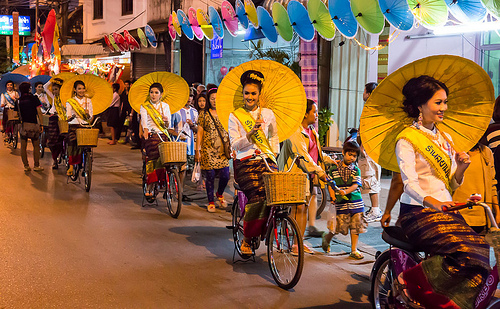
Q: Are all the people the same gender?
A: No, they are both male and female.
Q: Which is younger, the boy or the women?
A: The boy is younger than the women.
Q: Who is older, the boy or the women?
A: The women is older than the boy.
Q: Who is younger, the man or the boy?
A: The boy is younger than the man.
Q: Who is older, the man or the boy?
A: The man is older than the boy.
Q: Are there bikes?
A: Yes, there is a bike.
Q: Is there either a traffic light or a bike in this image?
A: Yes, there is a bike.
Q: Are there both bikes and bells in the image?
A: No, there is a bike but no bells.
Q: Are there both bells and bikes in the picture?
A: No, there is a bike but no bells.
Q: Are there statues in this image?
A: No, there are no statues.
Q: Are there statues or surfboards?
A: No, there are no statues or surfboards.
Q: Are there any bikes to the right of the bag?
A: Yes, there is a bike to the right of the bag.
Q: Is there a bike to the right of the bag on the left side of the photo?
A: Yes, there is a bike to the right of the bag.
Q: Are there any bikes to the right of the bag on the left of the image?
A: Yes, there is a bike to the right of the bag.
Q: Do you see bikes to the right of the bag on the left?
A: Yes, there is a bike to the right of the bag.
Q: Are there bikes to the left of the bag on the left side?
A: No, the bike is to the right of the bag.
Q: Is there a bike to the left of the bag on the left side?
A: No, the bike is to the right of the bag.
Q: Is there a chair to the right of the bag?
A: No, there is a bike to the right of the bag.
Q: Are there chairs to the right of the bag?
A: No, there is a bike to the right of the bag.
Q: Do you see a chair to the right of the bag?
A: No, there is a bike to the right of the bag.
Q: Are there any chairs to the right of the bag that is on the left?
A: No, there is a bike to the right of the bag.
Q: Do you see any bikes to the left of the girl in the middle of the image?
A: Yes, there is a bike to the left of the girl.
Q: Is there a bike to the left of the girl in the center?
A: Yes, there is a bike to the left of the girl.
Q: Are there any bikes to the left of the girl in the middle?
A: Yes, there is a bike to the left of the girl.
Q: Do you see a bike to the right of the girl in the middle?
A: No, the bike is to the left of the girl.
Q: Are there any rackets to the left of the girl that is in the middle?
A: No, there is a bike to the left of the girl.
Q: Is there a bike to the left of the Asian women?
A: Yes, there is a bike to the left of the women.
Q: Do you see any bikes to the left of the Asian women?
A: Yes, there is a bike to the left of the women.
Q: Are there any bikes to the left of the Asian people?
A: Yes, there is a bike to the left of the women.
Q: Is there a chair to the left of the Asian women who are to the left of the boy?
A: No, there is a bike to the left of the women.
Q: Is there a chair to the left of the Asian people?
A: No, there is a bike to the left of the women.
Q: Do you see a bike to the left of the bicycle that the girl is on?
A: Yes, there is a bike to the left of the bicycle.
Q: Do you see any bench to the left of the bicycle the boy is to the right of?
A: No, there is a bike to the left of the bicycle.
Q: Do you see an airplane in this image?
A: No, there are no airplanes.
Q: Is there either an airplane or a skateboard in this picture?
A: No, there are no airplanes or skateboards.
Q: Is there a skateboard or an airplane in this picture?
A: No, there are no airplanes or skateboards.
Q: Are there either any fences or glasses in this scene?
A: No, there are no fences or glasses.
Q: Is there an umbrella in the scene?
A: Yes, there is an umbrella.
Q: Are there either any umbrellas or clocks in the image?
A: Yes, there is an umbrella.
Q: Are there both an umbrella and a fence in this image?
A: No, there is an umbrella but no fences.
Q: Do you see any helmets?
A: No, there are no helmets.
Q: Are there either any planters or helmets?
A: No, there are no helmets or planters.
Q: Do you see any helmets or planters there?
A: No, there are no helmets or planters.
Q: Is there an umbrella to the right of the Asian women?
A: Yes, there is an umbrella to the right of the women.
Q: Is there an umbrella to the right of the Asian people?
A: Yes, there is an umbrella to the right of the women.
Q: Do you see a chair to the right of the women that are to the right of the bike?
A: No, there is an umbrella to the right of the women.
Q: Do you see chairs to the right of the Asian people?
A: No, there is an umbrella to the right of the women.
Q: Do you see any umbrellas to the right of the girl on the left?
A: Yes, there is an umbrella to the right of the girl.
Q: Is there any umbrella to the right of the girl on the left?
A: Yes, there is an umbrella to the right of the girl.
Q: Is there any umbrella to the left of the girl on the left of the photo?
A: No, the umbrella is to the right of the girl.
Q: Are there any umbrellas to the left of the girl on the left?
A: No, the umbrella is to the right of the girl.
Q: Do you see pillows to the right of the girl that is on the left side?
A: No, there is an umbrella to the right of the girl.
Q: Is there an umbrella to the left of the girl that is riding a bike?
A: Yes, there is an umbrella to the left of the girl.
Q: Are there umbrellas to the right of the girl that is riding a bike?
A: No, the umbrella is to the left of the girl.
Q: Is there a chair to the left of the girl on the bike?
A: No, there is an umbrella to the left of the girl.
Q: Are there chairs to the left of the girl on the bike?
A: No, there is an umbrella to the left of the girl.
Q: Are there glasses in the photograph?
A: No, there are no glasses.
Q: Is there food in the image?
A: No, there is no food.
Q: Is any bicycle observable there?
A: Yes, there is a bicycle.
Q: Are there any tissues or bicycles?
A: Yes, there is a bicycle.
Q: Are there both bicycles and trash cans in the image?
A: No, there is a bicycle but no trash cans.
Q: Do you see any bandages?
A: No, there are no bandages.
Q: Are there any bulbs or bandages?
A: No, there are no bandages or bulbs.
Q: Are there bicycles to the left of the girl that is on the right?
A: Yes, there is a bicycle to the left of the girl.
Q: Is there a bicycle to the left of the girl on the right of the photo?
A: Yes, there is a bicycle to the left of the girl.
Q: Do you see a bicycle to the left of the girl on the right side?
A: Yes, there is a bicycle to the left of the girl.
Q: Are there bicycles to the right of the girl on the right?
A: No, the bicycle is to the left of the girl.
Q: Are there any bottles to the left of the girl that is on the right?
A: No, there is a bicycle to the left of the girl.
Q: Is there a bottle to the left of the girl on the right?
A: No, there is a bicycle to the left of the girl.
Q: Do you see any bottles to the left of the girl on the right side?
A: No, there is a bicycle to the left of the girl.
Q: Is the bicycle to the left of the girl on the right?
A: Yes, the bicycle is to the left of the girl.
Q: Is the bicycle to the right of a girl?
A: No, the bicycle is to the left of a girl.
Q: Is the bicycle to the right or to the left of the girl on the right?
A: The bicycle is to the left of the girl.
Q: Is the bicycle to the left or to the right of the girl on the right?
A: The bicycle is to the left of the girl.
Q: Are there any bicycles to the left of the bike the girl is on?
A: Yes, there is a bicycle to the left of the bike.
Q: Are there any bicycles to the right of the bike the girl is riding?
A: No, the bicycle is to the left of the bike.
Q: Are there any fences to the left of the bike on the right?
A: No, there is a bicycle to the left of the bike.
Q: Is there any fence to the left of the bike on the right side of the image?
A: No, there is a bicycle to the left of the bike.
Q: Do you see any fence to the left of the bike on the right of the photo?
A: No, there is a bicycle to the left of the bike.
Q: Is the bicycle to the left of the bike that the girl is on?
A: Yes, the bicycle is to the left of the bike.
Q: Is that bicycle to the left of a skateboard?
A: No, the bicycle is to the left of the bike.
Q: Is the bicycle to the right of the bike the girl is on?
A: No, the bicycle is to the left of the bike.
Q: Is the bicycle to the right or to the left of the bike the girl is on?
A: The bicycle is to the left of the bike.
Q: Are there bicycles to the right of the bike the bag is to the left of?
A: Yes, there is a bicycle to the right of the bike.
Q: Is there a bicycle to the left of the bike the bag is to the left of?
A: No, the bicycle is to the right of the bike.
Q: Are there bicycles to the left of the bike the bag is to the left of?
A: No, the bicycle is to the right of the bike.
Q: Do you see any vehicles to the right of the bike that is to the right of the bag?
A: No, there is a bicycle to the right of the bike.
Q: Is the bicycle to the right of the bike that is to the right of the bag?
A: Yes, the bicycle is to the right of the bike.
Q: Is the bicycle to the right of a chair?
A: No, the bicycle is to the right of the bike.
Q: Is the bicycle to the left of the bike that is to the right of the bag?
A: No, the bicycle is to the right of the bike.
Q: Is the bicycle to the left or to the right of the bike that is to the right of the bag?
A: The bicycle is to the right of the bike.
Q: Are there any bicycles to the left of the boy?
A: Yes, there is a bicycle to the left of the boy.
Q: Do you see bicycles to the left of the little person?
A: Yes, there is a bicycle to the left of the boy.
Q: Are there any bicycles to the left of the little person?
A: Yes, there is a bicycle to the left of the boy.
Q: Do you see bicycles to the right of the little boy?
A: No, the bicycle is to the left of the boy.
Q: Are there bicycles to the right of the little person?
A: No, the bicycle is to the left of the boy.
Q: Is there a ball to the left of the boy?
A: No, there is a bicycle to the left of the boy.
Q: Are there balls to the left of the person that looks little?
A: No, there is a bicycle to the left of the boy.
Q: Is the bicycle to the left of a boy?
A: Yes, the bicycle is to the left of a boy.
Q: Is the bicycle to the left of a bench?
A: No, the bicycle is to the left of a boy.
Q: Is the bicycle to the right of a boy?
A: No, the bicycle is to the left of a boy.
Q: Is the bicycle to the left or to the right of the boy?
A: The bicycle is to the left of the boy.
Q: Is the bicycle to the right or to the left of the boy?
A: The bicycle is to the left of the boy.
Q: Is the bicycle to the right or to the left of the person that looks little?
A: The bicycle is to the left of the boy.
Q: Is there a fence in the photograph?
A: No, there are no fences.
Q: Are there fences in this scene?
A: No, there are no fences.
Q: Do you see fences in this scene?
A: No, there are no fences.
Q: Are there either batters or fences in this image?
A: No, there are no fences or batters.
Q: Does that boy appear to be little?
A: Yes, the boy is little.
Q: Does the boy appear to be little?
A: Yes, the boy is little.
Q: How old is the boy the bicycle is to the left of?
A: The boy is little.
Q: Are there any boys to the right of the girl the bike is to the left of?
A: Yes, there is a boy to the right of the girl.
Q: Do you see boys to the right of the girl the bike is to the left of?
A: Yes, there is a boy to the right of the girl.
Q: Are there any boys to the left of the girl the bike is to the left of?
A: No, the boy is to the right of the girl.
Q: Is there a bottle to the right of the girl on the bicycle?
A: No, there is a boy to the right of the girl.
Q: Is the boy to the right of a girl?
A: Yes, the boy is to the right of a girl.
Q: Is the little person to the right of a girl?
A: Yes, the boy is to the right of a girl.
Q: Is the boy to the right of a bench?
A: No, the boy is to the right of a girl.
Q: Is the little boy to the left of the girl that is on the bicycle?
A: No, the boy is to the right of the girl.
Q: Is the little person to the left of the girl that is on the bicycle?
A: No, the boy is to the right of the girl.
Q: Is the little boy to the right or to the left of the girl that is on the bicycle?
A: The boy is to the right of the girl.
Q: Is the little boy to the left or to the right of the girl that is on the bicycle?
A: The boy is to the right of the girl.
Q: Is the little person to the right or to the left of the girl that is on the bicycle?
A: The boy is to the right of the girl.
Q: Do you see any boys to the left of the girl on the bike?
A: Yes, there is a boy to the left of the girl.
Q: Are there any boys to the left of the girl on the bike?
A: Yes, there is a boy to the left of the girl.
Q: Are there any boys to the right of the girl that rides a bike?
A: No, the boy is to the left of the girl.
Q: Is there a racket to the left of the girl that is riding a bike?
A: No, there is a boy to the left of the girl.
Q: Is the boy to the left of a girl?
A: Yes, the boy is to the left of a girl.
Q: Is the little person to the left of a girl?
A: Yes, the boy is to the left of a girl.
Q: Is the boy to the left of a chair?
A: No, the boy is to the left of a girl.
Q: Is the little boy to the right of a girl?
A: No, the boy is to the left of a girl.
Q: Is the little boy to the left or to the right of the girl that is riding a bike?
A: The boy is to the left of the girl.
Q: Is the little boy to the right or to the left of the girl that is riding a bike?
A: The boy is to the left of the girl.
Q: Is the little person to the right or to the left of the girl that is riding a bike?
A: The boy is to the left of the girl.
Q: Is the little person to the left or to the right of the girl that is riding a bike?
A: The boy is to the left of the girl.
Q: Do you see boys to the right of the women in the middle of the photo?
A: Yes, there is a boy to the right of the women.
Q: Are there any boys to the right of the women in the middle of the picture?
A: Yes, there is a boy to the right of the women.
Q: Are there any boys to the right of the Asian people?
A: Yes, there is a boy to the right of the women.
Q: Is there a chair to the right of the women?
A: No, there is a boy to the right of the women.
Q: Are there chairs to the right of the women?
A: No, there is a boy to the right of the women.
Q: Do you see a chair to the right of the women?
A: No, there is a boy to the right of the women.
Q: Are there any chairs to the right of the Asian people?
A: No, there is a boy to the right of the women.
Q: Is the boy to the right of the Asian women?
A: Yes, the boy is to the right of the women.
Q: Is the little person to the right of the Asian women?
A: Yes, the boy is to the right of the women.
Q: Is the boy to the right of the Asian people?
A: Yes, the boy is to the right of the women.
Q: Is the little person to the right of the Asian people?
A: Yes, the boy is to the right of the women.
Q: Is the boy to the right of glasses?
A: No, the boy is to the right of the women.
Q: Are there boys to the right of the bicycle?
A: Yes, there is a boy to the right of the bicycle.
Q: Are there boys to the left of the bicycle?
A: No, the boy is to the right of the bicycle.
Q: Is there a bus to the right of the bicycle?
A: No, there is a boy to the right of the bicycle.